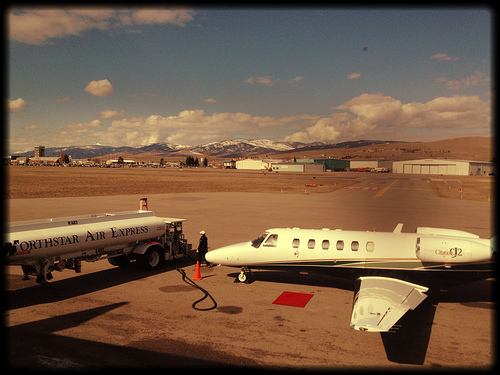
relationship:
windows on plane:
[291, 237, 376, 256] [204, 222, 493, 336]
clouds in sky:
[11, 7, 196, 46] [9, 8, 492, 145]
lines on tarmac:
[351, 174, 432, 202] [8, 174, 491, 369]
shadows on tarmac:
[6, 298, 254, 371] [8, 174, 491, 369]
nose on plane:
[202, 241, 254, 268] [204, 222, 493, 336]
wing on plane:
[349, 273, 431, 333] [204, 222, 493, 336]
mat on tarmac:
[272, 289, 315, 308] [8, 174, 491, 369]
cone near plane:
[189, 261, 203, 281] [204, 222, 493, 336]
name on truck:
[5, 220, 150, 254] [9, 209, 192, 286]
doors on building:
[403, 163, 457, 176] [393, 157, 492, 177]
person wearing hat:
[196, 228, 210, 268] [199, 228, 206, 236]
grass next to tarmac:
[6, 169, 359, 198] [8, 174, 491, 369]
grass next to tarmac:
[433, 176, 496, 202] [8, 174, 491, 369]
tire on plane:
[233, 269, 247, 283] [204, 222, 493, 336]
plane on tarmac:
[204, 222, 493, 336] [8, 174, 491, 369]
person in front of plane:
[196, 228, 210, 268] [204, 222, 493, 336]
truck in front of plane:
[9, 209, 192, 286] [204, 222, 493, 336]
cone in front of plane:
[189, 261, 203, 281] [204, 222, 493, 336]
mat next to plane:
[272, 289, 315, 308] [204, 222, 493, 336]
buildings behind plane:
[9, 145, 495, 177] [204, 222, 493, 336]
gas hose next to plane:
[167, 247, 218, 315] [204, 222, 493, 336]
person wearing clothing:
[196, 228, 210, 268] [197, 235, 210, 265]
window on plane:
[263, 231, 279, 249] [204, 222, 493, 336]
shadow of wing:
[382, 291, 440, 366] [349, 273, 431, 333]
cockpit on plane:
[250, 226, 286, 250] [204, 222, 493, 336]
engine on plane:
[413, 235, 494, 268] [204, 222, 493, 336]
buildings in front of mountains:
[9, 145, 495, 177] [15, 136, 405, 158]